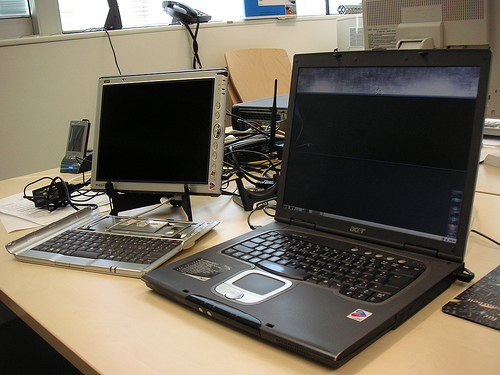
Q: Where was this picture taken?
A: Office setting.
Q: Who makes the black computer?
A: Acer.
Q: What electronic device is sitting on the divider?
A: Telephone.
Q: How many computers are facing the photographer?
A: 2.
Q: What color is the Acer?
A: Black.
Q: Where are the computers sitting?
A: Desk.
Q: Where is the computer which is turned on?
A: Right side.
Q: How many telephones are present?
A: 1.